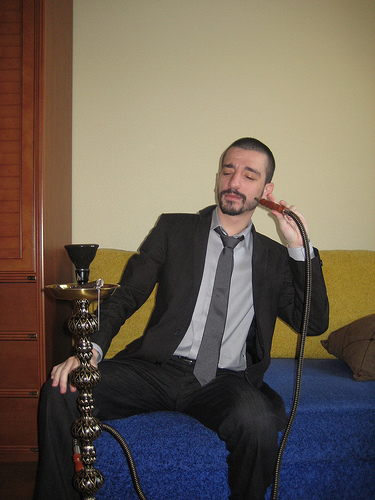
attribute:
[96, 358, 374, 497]
bedspread — royal blue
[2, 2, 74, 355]
protruding closet — large, wooden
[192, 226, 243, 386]
tie — grey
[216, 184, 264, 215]
beard — well-trimmed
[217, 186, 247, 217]
goatee — well-trimmed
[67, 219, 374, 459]
bed — large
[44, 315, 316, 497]
pants — lightweight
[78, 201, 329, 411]
jacket — dark grey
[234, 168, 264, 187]
eyes — closed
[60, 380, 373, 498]
bed — blue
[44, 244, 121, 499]
bong — big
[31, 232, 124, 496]
bowl — black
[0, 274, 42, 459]
dresser — wooden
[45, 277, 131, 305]
gold trimming — golden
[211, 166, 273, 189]
eye — closed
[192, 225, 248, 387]
tie — grey, loosened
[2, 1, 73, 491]
cabinet — wooden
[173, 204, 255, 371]
shirt — light gray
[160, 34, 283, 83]
wall — unadorned, beige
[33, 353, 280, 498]
pants — grey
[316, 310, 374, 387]
pillow — brown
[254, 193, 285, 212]
nozzle — mahogany, wooden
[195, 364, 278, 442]
pants — dark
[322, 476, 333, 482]
spot — light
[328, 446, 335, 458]
spot — light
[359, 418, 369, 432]
spot — light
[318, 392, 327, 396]
spot — dark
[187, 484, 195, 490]
spot — dark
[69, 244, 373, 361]
pillow — yellow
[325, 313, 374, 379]
pillow — brown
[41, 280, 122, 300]
ashtray — top